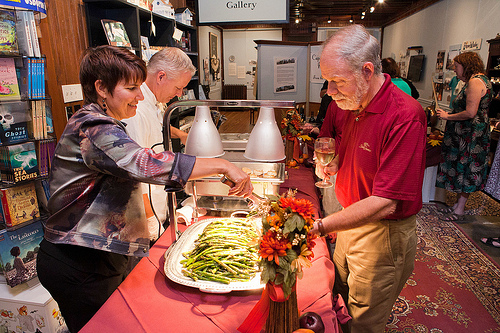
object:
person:
[34, 42, 254, 332]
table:
[80, 132, 354, 332]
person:
[122, 44, 199, 246]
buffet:
[240, 165, 283, 181]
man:
[307, 20, 430, 332]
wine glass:
[312, 134, 338, 190]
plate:
[162, 205, 266, 298]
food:
[179, 220, 261, 286]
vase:
[263, 268, 300, 333]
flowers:
[257, 228, 292, 267]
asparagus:
[190, 266, 231, 284]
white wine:
[314, 148, 335, 166]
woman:
[433, 49, 495, 227]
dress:
[435, 73, 493, 198]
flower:
[276, 193, 320, 228]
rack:
[2, 95, 48, 103]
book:
[28, 56, 35, 101]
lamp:
[239, 105, 289, 164]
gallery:
[224, 1, 260, 12]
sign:
[194, 0, 293, 26]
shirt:
[334, 72, 429, 222]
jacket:
[39, 103, 198, 260]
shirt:
[122, 83, 178, 242]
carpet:
[382, 205, 500, 332]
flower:
[303, 230, 317, 263]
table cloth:
[78, 166, 351, 332]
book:
[4, 141, 40, 185]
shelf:
[2, 172, 56, 186]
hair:
[318, 23, 386, 75]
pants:
[331, 215, 418, 332]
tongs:
[221, 169, 271, 208]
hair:
[78, 43, 147, 105]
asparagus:
[204, 247, 242, 274]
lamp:
[183, 103, 228, 159]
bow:
[236, 276, 299, 332]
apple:
[298, 308, 324, 332]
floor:
[374, 184, 499, 332]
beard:
[333, 73, 371, 114]